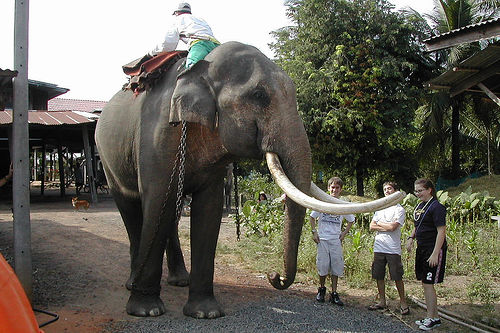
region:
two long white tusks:
[243, 111, 423, 249]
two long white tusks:
[284, 147, 429, 271]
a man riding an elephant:
[115, 0, 260, 104]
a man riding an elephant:
[144, 0, 379, 310]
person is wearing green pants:
[150, 1, 225, 73]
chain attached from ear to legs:
[140, 112, 180, 317]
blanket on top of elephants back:
[123, 44, 188, 94]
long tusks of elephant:
[263, 151, 406, 213]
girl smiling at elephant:
[413, 176, 446, 331]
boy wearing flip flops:
[370, 182, 410, 317]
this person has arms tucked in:
[368, 180, 406, 317]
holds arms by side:
[311, 178, 356, 305]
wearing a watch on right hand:
[310, 223, 317, 243]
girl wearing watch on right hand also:
[403, 231, 415, 247]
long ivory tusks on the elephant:
[256, 145, 411, 236]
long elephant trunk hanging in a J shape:
[264, 214, 304, 302]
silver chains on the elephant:
[159, 123, 195, 208]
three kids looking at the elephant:
[305, 165, 456, 330]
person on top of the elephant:
[131, 3, 230, 68]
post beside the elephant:
[10, 14, 47, 307]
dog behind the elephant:
[66, 183, 93, 225]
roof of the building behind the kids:
[420, 12, 490, 119]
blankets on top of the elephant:
[124, 52, 174, 103]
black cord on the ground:
[41, 291, 66, 328]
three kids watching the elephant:
[303, 158, 454, 313]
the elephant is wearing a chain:
[109, 135, 229, 325]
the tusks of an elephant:
[257, 147, 409, 217]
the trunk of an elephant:
[263, 147, 316, 292]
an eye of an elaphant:
[246, 85, 274, 112]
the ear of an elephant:
[166, 57, 220, 130]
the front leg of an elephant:
[184, 172, 226, 323]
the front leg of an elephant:
[124, 165, 181, 320]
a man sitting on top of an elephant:
[158, 0, 220, 92]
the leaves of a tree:
[330, 22, 381, 108]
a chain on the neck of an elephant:
[171, 121, 194, 216]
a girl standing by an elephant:
[405, 169, 457, 330]